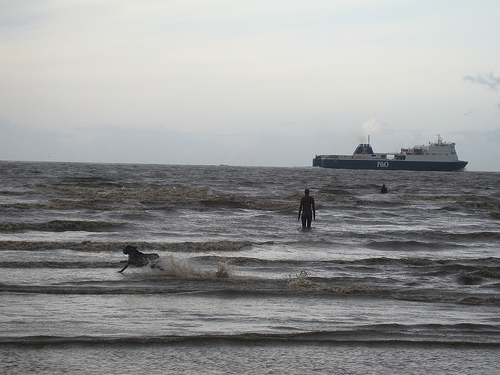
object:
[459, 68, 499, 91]
cloud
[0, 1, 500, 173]
sky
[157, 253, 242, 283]
waves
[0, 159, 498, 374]
water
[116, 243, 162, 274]
dog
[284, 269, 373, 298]
waves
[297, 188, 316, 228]
person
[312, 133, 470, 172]
ship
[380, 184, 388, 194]
person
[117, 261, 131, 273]
leg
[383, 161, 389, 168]
text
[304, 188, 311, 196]
head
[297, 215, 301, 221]
hand